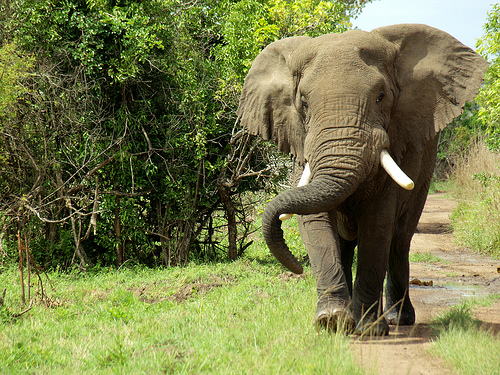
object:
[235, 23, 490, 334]
animal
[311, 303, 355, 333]
feet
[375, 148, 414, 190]
tusk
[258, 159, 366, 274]
trunk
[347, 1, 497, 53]
sky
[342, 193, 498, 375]
land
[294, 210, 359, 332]
legs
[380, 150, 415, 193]
tusk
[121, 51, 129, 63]
leaves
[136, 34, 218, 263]
tree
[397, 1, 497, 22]
clouds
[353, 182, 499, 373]
dirt path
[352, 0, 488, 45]
blue sky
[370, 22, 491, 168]
ear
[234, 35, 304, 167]
ear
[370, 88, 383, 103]
left eye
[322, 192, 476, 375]
path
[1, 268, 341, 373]
grass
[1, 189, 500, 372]
ground